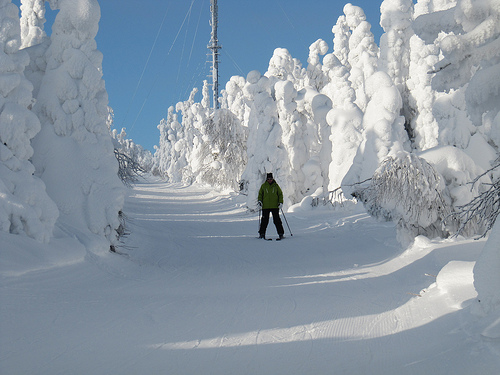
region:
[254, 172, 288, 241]
a dark figure on skis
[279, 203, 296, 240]
a black ski pole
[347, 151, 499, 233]
branches from a tree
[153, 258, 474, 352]
a stream of sunlight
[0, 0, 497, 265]
trees thickly covered in snow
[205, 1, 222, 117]
a power line pole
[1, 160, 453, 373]
a smooth snowy path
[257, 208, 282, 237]
black pants on a skier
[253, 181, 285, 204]
a black coat on a skier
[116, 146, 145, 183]
dead branches from a tree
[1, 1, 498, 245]
white snow packed trees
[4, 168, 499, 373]
snow covered ground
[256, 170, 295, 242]
a person wearing a green coat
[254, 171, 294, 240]
person holding ski poles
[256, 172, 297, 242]
person standing on skis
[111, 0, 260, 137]
electric lines covered with ice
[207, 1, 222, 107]
utility pole with ice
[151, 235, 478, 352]
sunlight shining on the ground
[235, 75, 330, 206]
shadows on the trees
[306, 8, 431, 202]
sunlight on the snow packed trees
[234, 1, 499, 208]
these are piles of snow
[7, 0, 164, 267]
snow has piled up over the trees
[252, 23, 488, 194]
the snow covers the trees completely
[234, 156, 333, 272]
this person is stopped on a hill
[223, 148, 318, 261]
this person is stopped on their skis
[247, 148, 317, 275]
his person is skiing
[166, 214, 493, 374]
shadows from the snow covered trees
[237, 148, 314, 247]
the jacket is green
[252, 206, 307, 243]
their pants are black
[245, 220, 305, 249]
their skis are black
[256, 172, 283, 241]
A man in a green coat and black pants.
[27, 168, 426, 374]
A smooth white ski slope.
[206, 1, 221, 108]
A tall pole coming out of the snow.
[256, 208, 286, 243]
Black pants on a skier.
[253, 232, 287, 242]
Two skis on a guy in green.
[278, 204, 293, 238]
Ski pole in a man's left hand.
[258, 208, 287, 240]
Black pants on a man.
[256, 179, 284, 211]
Green coat on a skier.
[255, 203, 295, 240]
Two black ski poles in the hands of a person.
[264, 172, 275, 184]
Head of a skier.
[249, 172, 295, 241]
skier in dark green jacket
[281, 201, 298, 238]
ski poles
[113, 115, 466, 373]
a skier in a long ski path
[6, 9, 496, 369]
a ski path with tall walls made of trees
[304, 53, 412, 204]
trees completely covered in snow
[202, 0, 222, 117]
a snow covered telephone pole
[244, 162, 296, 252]
a man on a skiing trip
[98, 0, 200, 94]
a bright blue sky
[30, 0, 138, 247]
a tree covered in a mound of snow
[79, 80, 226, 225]
a snowy trail